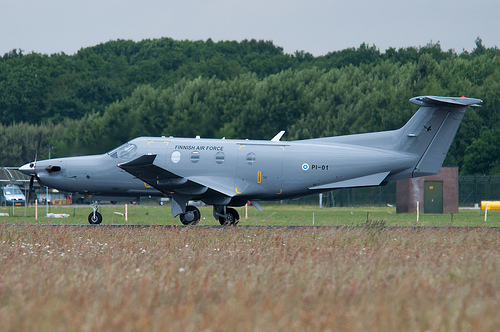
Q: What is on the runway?
A: Airplane.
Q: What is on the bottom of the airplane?
A: Tires.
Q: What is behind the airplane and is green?
A: Trees.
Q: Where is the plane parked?
A: On an airstrip.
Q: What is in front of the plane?
A: A dry field.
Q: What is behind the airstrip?
A: A thick forest.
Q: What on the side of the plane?
A: A fence.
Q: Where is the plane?
A: On the runway.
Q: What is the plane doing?
A: Waiting for repairs.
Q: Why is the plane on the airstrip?
A: For inspection.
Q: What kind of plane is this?
A: A military plane.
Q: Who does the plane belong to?
A: The air force.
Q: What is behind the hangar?
A: A forest.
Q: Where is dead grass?
A: In field.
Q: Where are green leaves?
A: On trees.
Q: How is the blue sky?
A: Clear cloudless.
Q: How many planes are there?
A: One.